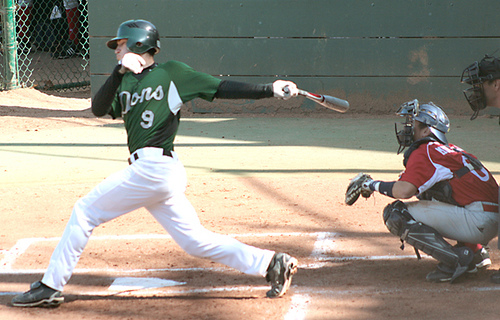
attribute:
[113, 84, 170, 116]
lettering — white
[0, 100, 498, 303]
dirt — brown 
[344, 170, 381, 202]
hand — gloved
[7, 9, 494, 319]
people — playing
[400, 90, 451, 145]
helmet — black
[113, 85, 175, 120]
letters — white 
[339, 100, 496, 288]
catcher — squatting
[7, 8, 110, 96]
fence — background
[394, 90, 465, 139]
hat — hard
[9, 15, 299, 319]
batter — hitting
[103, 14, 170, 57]
head — boys 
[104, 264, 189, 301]
base — home 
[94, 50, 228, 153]
top — green  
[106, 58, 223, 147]
jersey — green